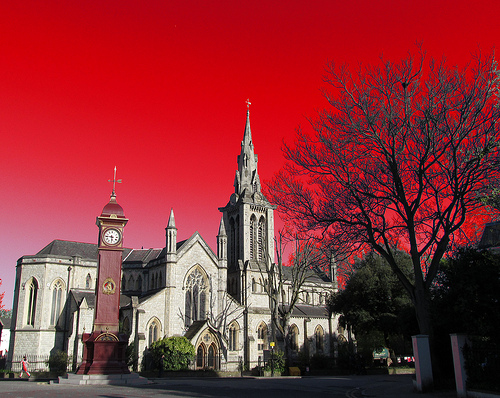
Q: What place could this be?
A: It is a church.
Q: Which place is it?
A: It is a church.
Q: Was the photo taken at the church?
A: Yes, it was taken in the church.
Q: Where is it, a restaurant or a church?
A: It is a church.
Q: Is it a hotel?
A: No, it is a church.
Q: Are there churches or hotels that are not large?
A: No, there is a church but it is large.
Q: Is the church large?
A: Yes, the church is large.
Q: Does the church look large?
A: Yes, the church is large.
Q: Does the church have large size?
A: Yes, the church is large.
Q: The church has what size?
A: The church is large.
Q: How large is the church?
A: The church is large.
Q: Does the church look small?
A: No, the church is large.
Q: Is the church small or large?
A: The church is large.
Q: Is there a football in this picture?
A: No, there are no footballs.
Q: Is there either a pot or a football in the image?
A: No, there are no footballs or pots.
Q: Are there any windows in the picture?
A: Yes, there is a window.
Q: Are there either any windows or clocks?
A: Yes, there is a window.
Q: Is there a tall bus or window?
A: Yes, there is a tall window.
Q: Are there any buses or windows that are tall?
A: Yes, the window is tall.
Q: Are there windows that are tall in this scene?
A: Yes, there is a tall window.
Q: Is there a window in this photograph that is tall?
A: Yes, there is a tall window.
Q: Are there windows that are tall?
A: Yes, there is a window that is tall.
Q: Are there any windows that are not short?
A: Yes, there is a tall window.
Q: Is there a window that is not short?
A: Yes, there is a tall window.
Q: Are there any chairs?
A: No, there are no chairs.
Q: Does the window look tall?
A: Yes, the window is tall.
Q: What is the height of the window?
A: The window is tall.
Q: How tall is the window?
A: The window is tall.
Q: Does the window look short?
A: No, the window is tall.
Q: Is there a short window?
A: No, there is a window but it is tall.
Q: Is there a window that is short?
A: No, there is a window but it is tall.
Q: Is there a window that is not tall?
A: No, there is a window but it is tall.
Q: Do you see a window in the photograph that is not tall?
A: No, there is a window but it is tall.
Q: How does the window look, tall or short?
A: The window is tall.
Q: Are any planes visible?
A: No, there are no planes.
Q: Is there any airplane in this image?
A: No, there are no airplanes.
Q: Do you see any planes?
A: No, there are no planes.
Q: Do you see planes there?
A: No, there are no planes.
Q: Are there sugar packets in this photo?
A: No, there are no sugar packets.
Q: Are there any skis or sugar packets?
A: No, there are no sugar packets or skis.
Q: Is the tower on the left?
A: Yes, the tower is on the left of the image.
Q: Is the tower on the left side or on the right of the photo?
A: The tower is on the left of the image.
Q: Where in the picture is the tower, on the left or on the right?
A: The tower is on the left of the image.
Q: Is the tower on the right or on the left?
A: The tower is on the left of the image.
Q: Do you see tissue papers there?
A: No, there are no tissue papers.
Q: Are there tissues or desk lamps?
A: No, there are no tissues or desk lamps.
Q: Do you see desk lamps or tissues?
A: No, there are no tissues or desk lamps.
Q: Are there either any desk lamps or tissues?
A: No, there are no tissues or desk lamps.